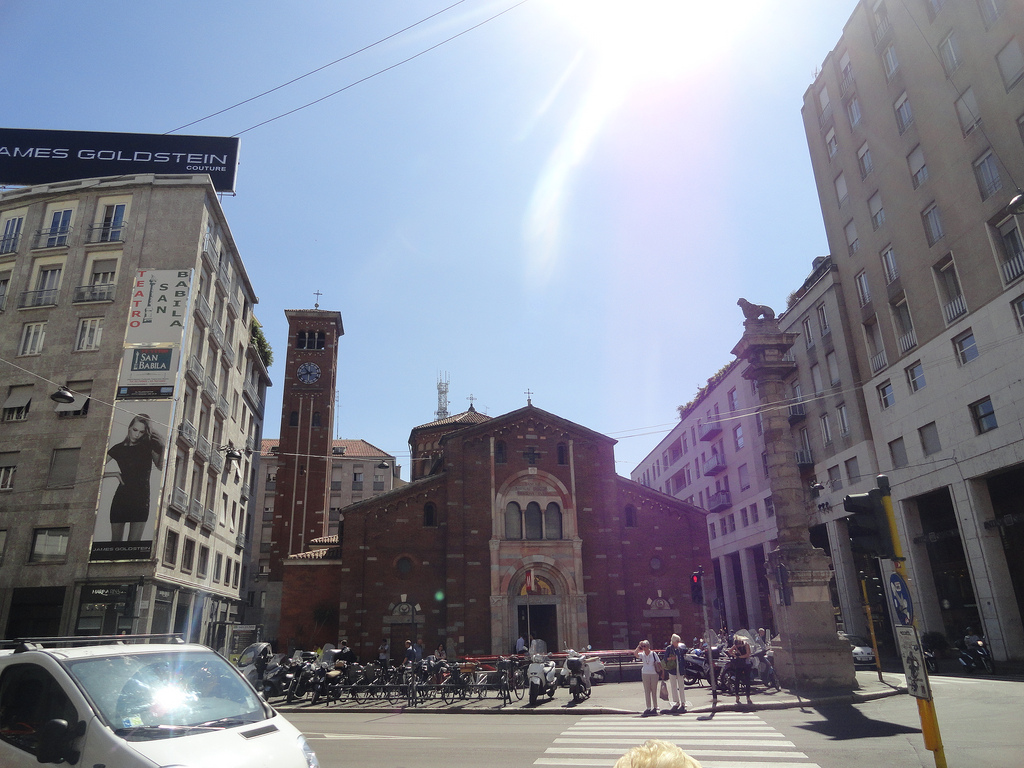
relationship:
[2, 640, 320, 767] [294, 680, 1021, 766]
white car on street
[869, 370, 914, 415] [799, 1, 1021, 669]
window on building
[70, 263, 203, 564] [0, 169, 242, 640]
advertisment on side of building